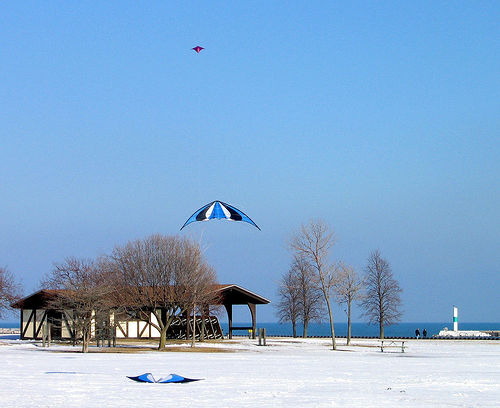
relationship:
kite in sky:
[184, 30, 217, 69] [99, 62, 390, 165]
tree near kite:
[278, 206, 408, 344] [184, 30, 217, 69]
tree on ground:
[278, 206, 408, 344] [236, 341, 390, 394]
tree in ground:
[278, 206, 408, 344] [236, 341, 390, 394]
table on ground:
[365, 318, 416, 363] [236, 341, 390, 394]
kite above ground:
[184, 30, 217, 69] [236, 341, 390, 394]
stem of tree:
[324, 305, 340, 347] [278, 206, 408, 344]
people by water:
[368, 312, 444, 349] [309, 304, 398, 332]